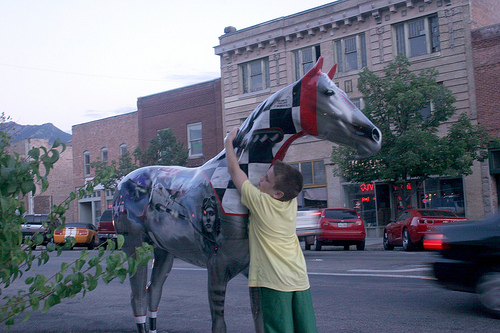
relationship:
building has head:
[0, 0, 500, 255] [291, 54, 384, 162]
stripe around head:
[298, 53, 324, 140] [291, 54, 384, 162]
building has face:
[0, 0, 500, 255] [313, 70, 383, 157]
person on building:
[200, 197, 220, 252] [0, 0, 500, 255]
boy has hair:
[225, 126, 317, 332] [271, 156, 305, 204]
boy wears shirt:
[225, 126, 317, 332] [238, 180, 310, 294]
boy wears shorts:
[225, 126, 317, 332] [256, 284, 319, 332]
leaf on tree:
[114, 232, 127, 249] [2, 113, 158, 332]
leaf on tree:
[96, 244, 107, 262] [2, 113, 158, 332]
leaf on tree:
[50, 147, 61, 167] [2, 113, 158, 332]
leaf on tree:
[41, 174, 50, 197] [2, 113, 158, 332]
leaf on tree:
[18, 180, 34, 198] [2, 113, 158, 332]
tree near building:
[2, 113, 158, 332] [0, 0, 500, 255]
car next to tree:
[383, 205, 469, 250] [327, 48, 493, 209]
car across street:
[383, 205, 469, 250] [1, 245, 500, 333]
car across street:
[52, 220, 101, 251] [1, 245, 500, 333]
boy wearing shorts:
[225, 126, 317, 332] [256, 284, 319, 332]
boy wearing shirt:
[225, 126, 317, 332] [238, 180, 310, 294]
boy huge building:
[225, 126, 317, 332] [0, 0, 500, 255]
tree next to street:
[327, 48, 493, 209] [1, 245, 500, 333]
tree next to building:
[2, 113, 158, 332] [0, 0, 500, 255]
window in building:
[331, 30, 370, 79] [213, 1, 497, 250]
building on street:
[0, 0, 500, 255] [1, 245, 500, 333]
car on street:
[383, 205, 469, 250] [1, 245, 500, 333]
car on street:
[52, 220, 101, 251] [1, 245, 500, 333]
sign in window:
[358, 182, 376, 194] [349, 182, 390, 229]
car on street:
[16, 213, 61, 250] [1, 245, 500, 333]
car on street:
[417, 214, 499, 314] [1, 245, 500, 333]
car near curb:
[383, 205, 469, 250] [310, 240, 390, 252]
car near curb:
[302, 204, 370, 253] [310, 240, 390, 252]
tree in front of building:
[327, 48, 493, 209] [213, 1, 497, 250]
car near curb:
[52, 220, 101, 251] [23, 239, 117, 249]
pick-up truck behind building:
[291, 205, 322, 253] [0, 0, 500, 255]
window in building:
[388, 8, 443, 65] [213, 1, 497, 250]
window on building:
[236, 56, 273, 97] [213, 1, 497, 250]